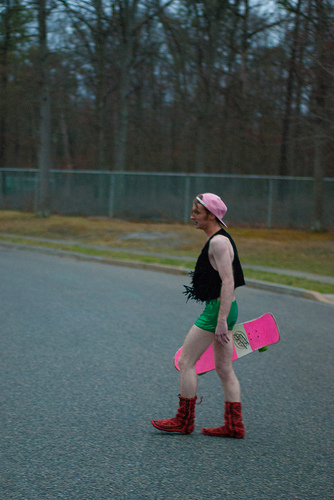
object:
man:
[150, 192, 248, 441]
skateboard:
[172, 310, 281, 376]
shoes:
[200, 401, 246, 441]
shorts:
[194, 298, 239, 334]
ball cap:
[195, 192, 229, 231]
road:
[0, 244, 334, 499]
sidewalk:
[247, 263, 320, 284]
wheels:
[258, 345, 268, 352]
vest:
[182, 227, 246, 306]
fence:
[0, 165, 334, 232]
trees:
[157, 0, 271, 226]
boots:
[150, 393, 198, 436]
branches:
[251, 17, 292, 51]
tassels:
[182, 283, 194, 304]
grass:
[265, 236, 316, 275]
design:
[232, 330, 249, 350]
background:
[0, 0, 334, 234]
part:
[124, 247, 162, 258]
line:
[236, 332, 250, 345]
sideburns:
[203, 208, 211, 222]